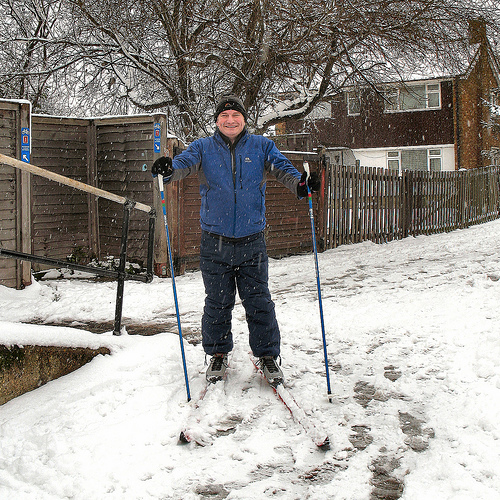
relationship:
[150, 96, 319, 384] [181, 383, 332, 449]
man on skis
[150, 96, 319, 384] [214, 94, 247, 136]
man has head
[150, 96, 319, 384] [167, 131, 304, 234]
man has jacket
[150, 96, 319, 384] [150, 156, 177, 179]
man has glove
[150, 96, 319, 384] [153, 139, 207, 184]
man has arm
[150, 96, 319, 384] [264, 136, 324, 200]
man has arm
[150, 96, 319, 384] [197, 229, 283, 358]
man wearing snow pants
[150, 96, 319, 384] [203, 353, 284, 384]
man wearing shoes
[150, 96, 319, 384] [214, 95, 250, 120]
man wearing cap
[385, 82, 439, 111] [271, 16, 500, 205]
window on house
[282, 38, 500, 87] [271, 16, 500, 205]
roof on house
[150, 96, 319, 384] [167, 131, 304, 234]
man wearing jacket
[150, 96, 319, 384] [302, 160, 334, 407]
man holding pole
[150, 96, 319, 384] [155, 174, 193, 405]
man holding pole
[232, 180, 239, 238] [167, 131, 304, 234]
zipper on jacket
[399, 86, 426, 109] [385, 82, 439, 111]
pane on window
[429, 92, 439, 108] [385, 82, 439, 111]
pane on window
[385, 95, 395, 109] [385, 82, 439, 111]
pane on window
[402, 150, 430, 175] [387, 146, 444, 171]
pane on window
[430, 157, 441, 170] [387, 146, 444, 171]
pane on window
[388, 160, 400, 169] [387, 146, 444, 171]
pane on window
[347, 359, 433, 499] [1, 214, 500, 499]
footprints in snow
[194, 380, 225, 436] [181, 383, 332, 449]
snow on skis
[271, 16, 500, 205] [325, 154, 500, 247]
house behind fence